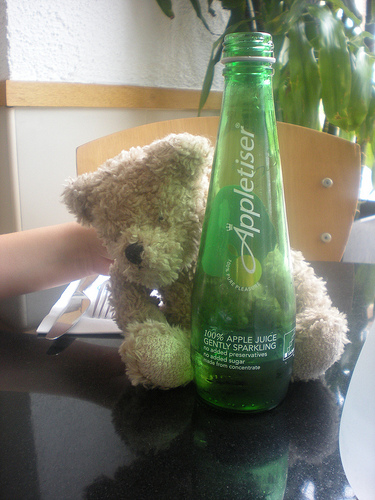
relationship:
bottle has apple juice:
[190, 32, 295, 416] [198, 21, 306, 417]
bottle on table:
[190, 32, 295, 416] [1, 261, 373, 498]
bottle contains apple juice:
[190, 32, 295, 416] [191, 344, 296, 413]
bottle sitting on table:
[190, 32, 295, 416] [1, 261, 373, 498]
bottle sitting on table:
[190, 32, 295, 416] [145, 432, 288, 497]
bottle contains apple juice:
[208, 43, 304, 337] [191, 344, 296, 413]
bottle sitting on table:
[208, 43, 304, 337] [1, 261, 373, 498]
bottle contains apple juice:
[190, 32, 295, 416] [200, 327, 277, 370]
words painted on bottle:
[204, 329, 279, 352] [190, 32, 295, 416]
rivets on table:
[320, 173, 338, 246] [1, 261, 373, 498]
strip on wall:
[0, 79, 222, 110] [2, 0, 374, 244]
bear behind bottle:
[72, 121, 356, 401] [190, 32, 295, 416]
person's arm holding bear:
[1, 220, 115, 301] [60, 133, 352, 390]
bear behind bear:
[60, 133, 352, 390] [58, 131, 349, 390]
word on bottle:
[234, 125, 260, 273] [190, 32, 295, 416]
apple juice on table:
[190, 345, 293, 412] [1, 261, 373, 498]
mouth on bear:
[112, 235, 170, 287] [60, 133, 352, 390]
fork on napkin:
[96, 281, 112, 316] [45, 267, 124, 339]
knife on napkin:
[49, 279, 89, 342] [45, 267, 124, 339]